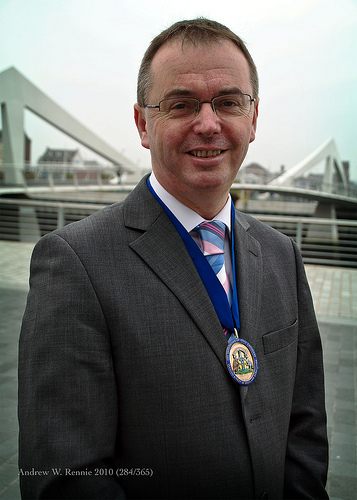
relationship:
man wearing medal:
[17, 13, 343, 499] [144, 175, 263, 386]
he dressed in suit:
[17, 13, 343, 499] [15, 170, 336, 495]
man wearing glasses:
[17, 13, 343, 499] [136, 92, 260, 125]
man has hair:
[17, 13, 343, 499] [151, 18, 245, 55]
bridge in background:
[3, 58, 136, 230] [10, 175, 140, 191]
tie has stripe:
[196, 221, 236, 313] [201, 239, 224, 257]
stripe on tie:
[202, 227, 225, 247] [196, 221, 236, 313]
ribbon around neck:
[144, 175, 263, 386] [149, 157, 255, 227]